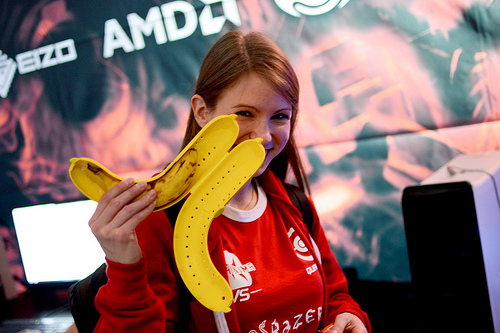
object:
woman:
[87, 24, 372, 333]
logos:
[222, 250, 261, 306]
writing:
[101, 0, 244, 58]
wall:
[0, 0, 500, 302]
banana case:
[67, 112, 265, 314]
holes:
[183, 245, 189, 249]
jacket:
[92, 167, 371, 333]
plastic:
[170, 137, 268, 314]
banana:
[85, 147, 198, 211]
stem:
[86, 162, 115, 185]